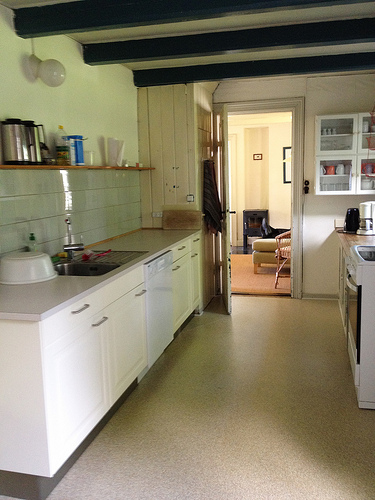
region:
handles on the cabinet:
[75, 303, 110, 336]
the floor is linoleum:
[160, 355, 359, 486]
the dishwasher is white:
[144, 257, 188, 375]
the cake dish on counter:
[3, 249, 65, 290]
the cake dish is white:
[0, 251, 62, 291]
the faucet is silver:
[61, 208, 82, 263]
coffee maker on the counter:
[358, 204, 372, 236]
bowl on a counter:
[1, 248, 59, 287]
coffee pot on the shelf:
[7, 116, 35, 159]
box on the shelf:
[49, 133, 79, 163]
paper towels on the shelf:
[105, 132, 125, 166]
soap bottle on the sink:
[24, 226, 35, 252]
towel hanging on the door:
[200, 149, 221, 233]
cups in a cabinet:
[320, 161, 351, 174]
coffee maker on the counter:
[355, 199, 374, 238]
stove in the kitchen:
[345, 241, 373, 410]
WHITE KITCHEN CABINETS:
[2, 228, 205, 476]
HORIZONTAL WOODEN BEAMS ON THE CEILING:
[6, 2, 372, 122]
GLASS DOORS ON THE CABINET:
[313, 108, 374, 194]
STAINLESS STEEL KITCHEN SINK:
[40, 204, 148, 283]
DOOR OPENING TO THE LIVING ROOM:
[208, 108, 315, 316]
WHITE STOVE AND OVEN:
[342, 238, 374, 403]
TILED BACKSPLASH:
[0, 163, 157, 259]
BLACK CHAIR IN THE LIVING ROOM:
[235, 201, 279, 254]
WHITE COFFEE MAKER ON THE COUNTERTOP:
[350, 195, 373, 240]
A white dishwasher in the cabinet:
[136, 249, 181, 364]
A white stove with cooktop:
[342, 243, 374, 413]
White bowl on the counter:
[0, 243, 54, 286]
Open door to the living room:
[206, 115, 236, 316]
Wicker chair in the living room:
[268, 222, 288, 293]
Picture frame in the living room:
[279, 141, 288, 187]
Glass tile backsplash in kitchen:
[0, 172, 138, 253]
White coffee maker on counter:
[356, 199, 372, 234]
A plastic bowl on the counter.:
[7, 247, 65, 293]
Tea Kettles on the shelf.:
[4, 115, 46, 169]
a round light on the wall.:
[8, 55, 83, 96]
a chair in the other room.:
[263, 230, 290, 278]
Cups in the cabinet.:
[321, 162, 374, 179]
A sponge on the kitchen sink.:
[47, 245, 71, 263]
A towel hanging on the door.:
[199, 159, 230, 240]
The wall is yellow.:
[234, 124, 283, 201]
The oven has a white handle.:
[340, 271, 367, 298]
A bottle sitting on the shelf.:
[50, 127, 73, 170]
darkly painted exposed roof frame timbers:
[11, 0, 373, 91]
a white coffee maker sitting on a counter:
[353, 200, 373, 238]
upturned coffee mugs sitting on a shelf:
[319, 161, 350, 177]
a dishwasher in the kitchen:
[137, 245, 183, 363]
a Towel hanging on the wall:
[196, 151, 224, 241]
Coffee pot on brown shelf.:
[1, 116, 41, 163]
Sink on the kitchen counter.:
[47, 215, 141, 276]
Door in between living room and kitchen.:
[216, 105, 302, 297]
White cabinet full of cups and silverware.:
[313, 113, 374, 197]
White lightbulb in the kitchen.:
[28, 55, 69, 89]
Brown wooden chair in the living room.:
[273, 225, 291, 290]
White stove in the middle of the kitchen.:
[343, 243, 374, 407]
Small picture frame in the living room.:
[250, 152, 264, 161]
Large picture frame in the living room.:
[279, 144, 290, 187]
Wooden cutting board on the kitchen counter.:
[160, 206, 204, 231]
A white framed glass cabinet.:
[311, 113, 373, 197]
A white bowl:
[1, 249, 59, 282]